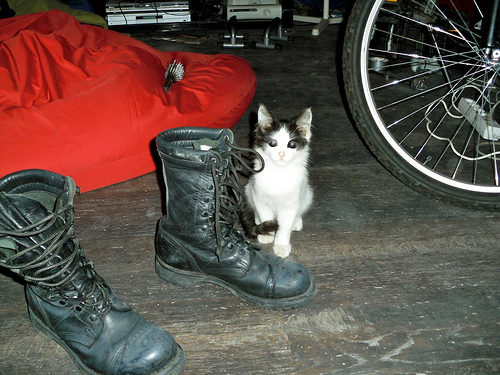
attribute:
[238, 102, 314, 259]
cat — sitting, black, white, multi colored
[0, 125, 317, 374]
boots — dark, black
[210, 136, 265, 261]
laces — black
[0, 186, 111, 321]
laces — black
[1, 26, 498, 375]
floor — scratched, old, beat up, dirty, scuffed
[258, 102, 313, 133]
ears — pointy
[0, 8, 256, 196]
cushion — red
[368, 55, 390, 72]
duct tape — rolled, gray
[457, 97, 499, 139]
surge protector — white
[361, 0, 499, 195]
stripe — white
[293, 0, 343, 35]
base — white